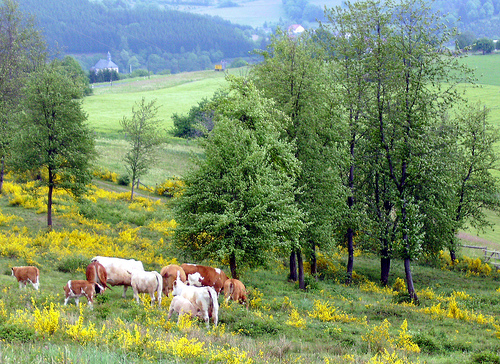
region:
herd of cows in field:
[11, 232, 251, 330]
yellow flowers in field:
[51, 195, 155, 259]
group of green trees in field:
[220, 55, 466, 277]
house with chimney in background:
[82, 35, 134, 80]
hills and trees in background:
[22, 7, 252, 64]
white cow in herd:
[175, 279, 235, 324]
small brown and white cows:
[11, 241, 98, 330]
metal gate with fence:
[437, 225, 498, 280]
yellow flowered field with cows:
[12, 172, 322, 342]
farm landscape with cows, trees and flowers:
[18, 19, 473, 333]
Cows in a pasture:
[0, 233, 290, 342]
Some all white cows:
[92, 247, 225, 327]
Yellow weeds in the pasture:
[8, 172, 494, 360]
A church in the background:
[82, 45, 137, 83]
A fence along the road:
[462, 238, 498, 273]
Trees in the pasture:
[11, 19, 491, 313]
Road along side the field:
[82, 167, 482, 276]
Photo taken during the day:
[12, 7, 492, 352]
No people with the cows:
[2, 5, 487, 353]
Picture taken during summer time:
[5, 8, 492, 355]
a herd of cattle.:
[11, 217, 266, 348]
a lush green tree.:
[170, 48, 313, 283]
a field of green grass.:
[50, 56, 496, 197]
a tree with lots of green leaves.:
[164, 49, 314, 285]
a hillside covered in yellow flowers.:
[3, 150, 496, 362]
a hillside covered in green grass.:
[30, 36, 494, 203]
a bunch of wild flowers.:
[2, 153, 498, 351]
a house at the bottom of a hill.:
[84, 31, 146, 104]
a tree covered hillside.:
[0, 1, 290, 88]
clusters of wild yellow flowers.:
[263, 265, 459, 360]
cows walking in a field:
[6, 230, 266, 340]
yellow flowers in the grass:
[57, 290, 222, 362]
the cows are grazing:
[33, 233, 260, 320]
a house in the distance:
[82, 43, 139, 85]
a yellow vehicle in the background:
[206, 55, 251, 77]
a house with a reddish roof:
[256, 10, 316, 45]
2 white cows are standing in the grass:
[157, 278, 228, 323]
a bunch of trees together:
[163, 0, 451, 313]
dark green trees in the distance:
[60, 3, 246, 63]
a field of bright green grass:
[115, 64, 314, 126]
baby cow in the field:
[10, 257, 52, 293]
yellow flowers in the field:
[32, 293, 89, 350]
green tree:
[140, 72, 312, 312]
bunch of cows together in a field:
[7, 245, 282, 345]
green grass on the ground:
[415, 323, 455, 348]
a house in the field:
[76, 45, 129, 104]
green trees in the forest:
[70, 12, 237, 57]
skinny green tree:
[110, 96, 175, 208]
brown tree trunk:
[395, 255, 436, 305]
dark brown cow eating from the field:
[174, 249, 264, 312]